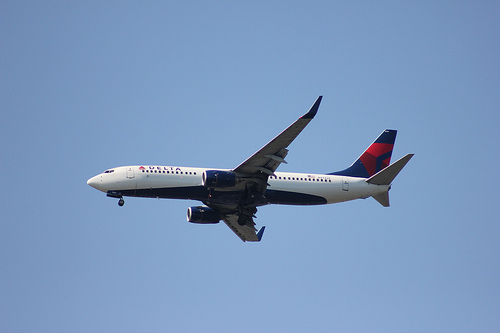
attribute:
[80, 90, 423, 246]
plane — white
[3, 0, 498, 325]
sky — clear, blue, with no clouds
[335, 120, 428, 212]
tail — blue, red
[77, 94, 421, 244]
airplane — white, red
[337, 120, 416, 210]
tail — blue